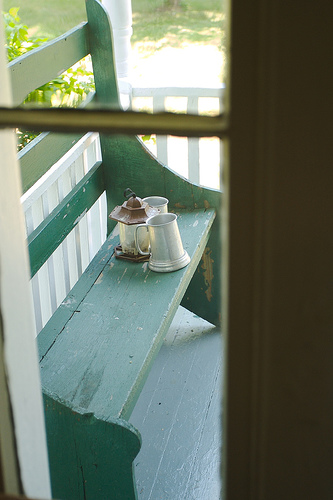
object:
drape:
[0, 7, 53, 497]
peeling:
[199, 243, 217, 304]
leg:
[103, 132, 221, 328]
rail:
[185, 96, 200, 181]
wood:
[8, 0, 220, 497]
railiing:
[131, 83, 224, 118]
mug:
[141, 195, 169, 214]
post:
[102, 0, 130, 87]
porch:
[0, 2, 228, 497]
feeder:
[108, 191, 159, 264]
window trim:
[0, 106, 229, 139]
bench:
[7, 0, 220, 499]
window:
[0, 1, 232, 498]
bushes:
[1, 2, 94, 140]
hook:
[123, 188, 135, 197]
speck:
[158, 402, 161, 406]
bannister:
[26, 164, 72, 197]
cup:
[133, 206, 189, 270]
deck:
[37, 302, 219, 497]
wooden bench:
[15, 5, 221, 500]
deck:
[128, 305, 233, 497]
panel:
[0, 2, 235, 494]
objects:
[109, 187, 192, 272]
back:
[6, 21, 108, 356]